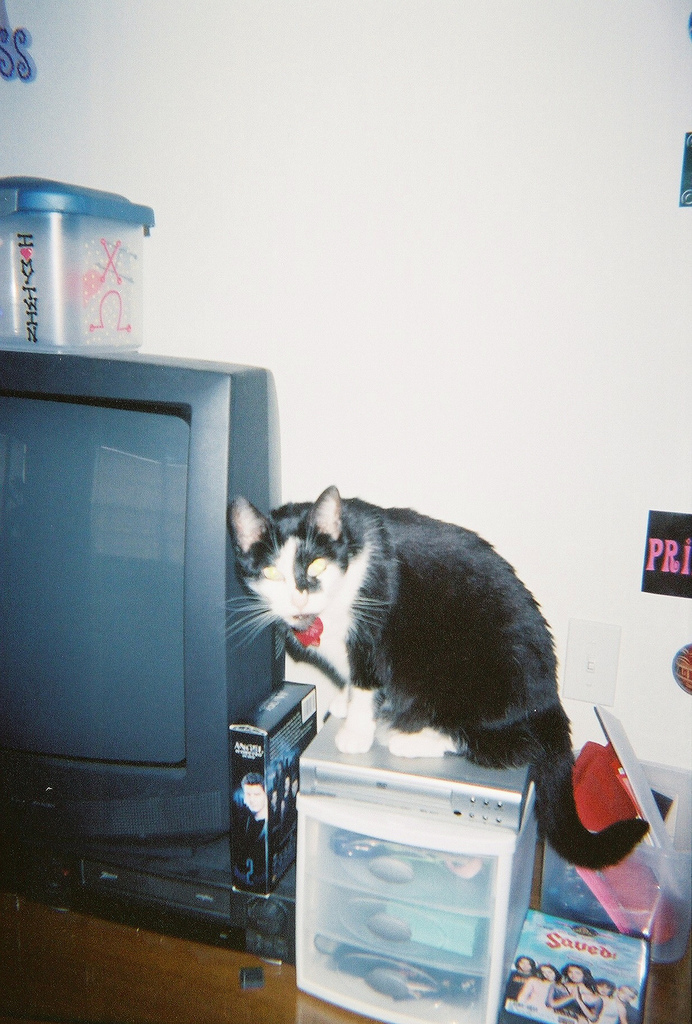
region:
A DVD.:
[496, 886, 641, 1017]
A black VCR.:
[39, 844, 287, 967]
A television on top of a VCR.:
[2, 336, 268, 852]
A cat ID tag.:
[287, 609, 316, 649]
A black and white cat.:
[221, 511, 652, 857]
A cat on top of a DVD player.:
[212, 467, 648, 872]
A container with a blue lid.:
[1, 173, 146, 357]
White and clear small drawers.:
[281, 799, 516, 1015]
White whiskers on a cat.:
[224, 594, 391, 640]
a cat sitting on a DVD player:
[227, 497, 644, 843]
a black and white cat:
[232, 491, 658, 866]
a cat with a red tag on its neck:
[226, 491, 363, 675]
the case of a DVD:
[504, 906, 650, 1016]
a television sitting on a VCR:
[2, 349, 284, 932]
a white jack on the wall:
[552, 601, 629, 708]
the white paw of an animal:
[335, 681, 382, 754]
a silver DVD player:
[297, 721, 529, 825]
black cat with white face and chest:
[222, 484, 654, 874]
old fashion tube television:
[0, 346, 285, 883]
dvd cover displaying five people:
[496, 904, 656, 1022]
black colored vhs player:
[0, 803, 299, 970]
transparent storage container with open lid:
[537, 704, 690, 969]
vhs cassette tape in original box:
[220, 675, 316, 899]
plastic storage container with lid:
[2, 173, 156, 365]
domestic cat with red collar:
[225, 482, 652, 875]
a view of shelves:
[329, 835, 511, 990]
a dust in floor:
[225, 951, 300, 1021]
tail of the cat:
[534, 757, 659, 875]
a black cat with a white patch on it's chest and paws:
[228, 482, 648, 871]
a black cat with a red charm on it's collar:
[232, 484, 651, 884]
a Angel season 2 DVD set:
[233, 678, 322, 899]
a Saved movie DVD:
[500, 900, 655, 1021]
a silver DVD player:
[295, 706, 533, 827]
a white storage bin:
[289, 791, 545, 1019]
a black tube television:
[3, 340, 282, 852]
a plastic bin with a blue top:
[5, 169, 159, 352]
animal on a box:
[223, 488, 657, 1020]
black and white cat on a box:
[229, 487, 651, 1021]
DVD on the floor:
[500, 905, 651, 1021]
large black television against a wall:
[2, 334, 281, 855]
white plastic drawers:
[290, 791, 522, 1022]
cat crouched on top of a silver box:
[222, 488, 633, 1021]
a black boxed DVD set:
[225, 674, 317, 900]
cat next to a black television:
[1, 345, 654, 954]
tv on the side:
[25, 303, 288, 937]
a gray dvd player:
[297, 725, 532, 838]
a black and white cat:
[216, 474, 654, 873]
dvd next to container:
[505, 894, 648, 1019]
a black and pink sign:
[639, 490, 690, 608]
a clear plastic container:
[267, 787, 519, 1009]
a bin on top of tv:
[19, 178, 166, 354]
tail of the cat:
[543, 734, 680, 894]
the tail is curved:
[521, 742, 661, 881]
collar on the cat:
[278, 609, 343, 671]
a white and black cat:
[197, 429, 594, 763]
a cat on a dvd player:
[218, 543, 561, 807]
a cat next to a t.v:
[37, 512, 429, 874]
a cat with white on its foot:
[266, 583, 449, 777]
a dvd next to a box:
[391, 896, 660, 1021]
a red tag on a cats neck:
[254, 595, 339, 698]